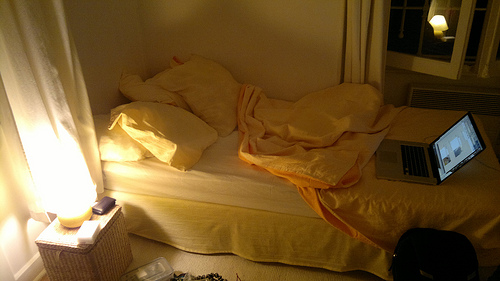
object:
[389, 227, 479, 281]
object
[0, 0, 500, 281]
room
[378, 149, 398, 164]
track pad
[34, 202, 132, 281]
nightstand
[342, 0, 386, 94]
curtain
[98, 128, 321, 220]
sheet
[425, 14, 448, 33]
light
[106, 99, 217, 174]
pillow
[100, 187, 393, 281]
skirt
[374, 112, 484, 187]
lap top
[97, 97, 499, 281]
bed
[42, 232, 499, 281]
floor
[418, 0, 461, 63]
reflection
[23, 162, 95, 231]
lamp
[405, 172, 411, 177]
keys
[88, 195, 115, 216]
object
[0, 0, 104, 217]
curtain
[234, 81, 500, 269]
blanket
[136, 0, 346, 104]
wall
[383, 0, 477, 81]
window